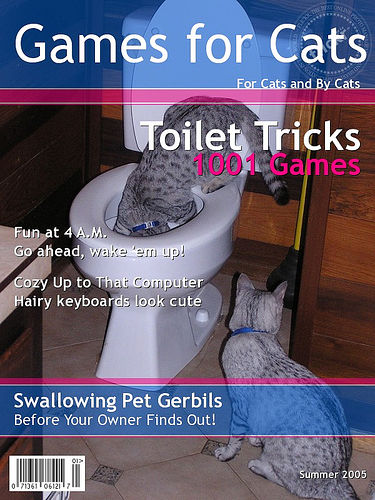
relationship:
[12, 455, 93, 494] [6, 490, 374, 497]
upc symbol on bottom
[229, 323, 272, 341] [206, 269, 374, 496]
collar on cat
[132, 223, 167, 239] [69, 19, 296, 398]
head in toilet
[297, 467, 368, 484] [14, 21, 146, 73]
date for game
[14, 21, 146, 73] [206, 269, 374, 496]
game for cat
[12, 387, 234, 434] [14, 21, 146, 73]
tagline for game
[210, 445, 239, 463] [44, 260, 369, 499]
left paw on floor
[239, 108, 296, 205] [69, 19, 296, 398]
tail hanging off toilet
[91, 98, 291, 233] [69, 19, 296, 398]
cat in toilet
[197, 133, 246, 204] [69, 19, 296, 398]
back legs on toilet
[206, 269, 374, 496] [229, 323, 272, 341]
cat has collar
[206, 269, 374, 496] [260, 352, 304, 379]
cat has spots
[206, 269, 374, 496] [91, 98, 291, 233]
cat by cat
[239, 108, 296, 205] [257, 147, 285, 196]
tail has stripes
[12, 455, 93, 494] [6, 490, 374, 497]
upc symbol at bottom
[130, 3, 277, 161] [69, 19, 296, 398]
lid to toilet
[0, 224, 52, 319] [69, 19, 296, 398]
countertop next to toilet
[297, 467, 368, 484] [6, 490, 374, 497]
date on bottom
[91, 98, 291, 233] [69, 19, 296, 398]
cat looking in toilet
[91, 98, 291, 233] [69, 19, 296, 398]
cat in a toilet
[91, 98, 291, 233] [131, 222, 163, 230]
cat has collar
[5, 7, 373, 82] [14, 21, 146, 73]
title for game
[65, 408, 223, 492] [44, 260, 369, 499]
tile on floor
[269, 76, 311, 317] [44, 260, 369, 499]
plunger on floor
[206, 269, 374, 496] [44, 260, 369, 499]
cat sitting on floor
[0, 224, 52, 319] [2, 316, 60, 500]
countertop on vanity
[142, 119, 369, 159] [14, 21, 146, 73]
toilet tricks for game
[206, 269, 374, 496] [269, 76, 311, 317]
cat looking at plunger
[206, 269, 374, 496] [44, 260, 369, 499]
cat on floor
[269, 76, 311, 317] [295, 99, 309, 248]
plunger has handle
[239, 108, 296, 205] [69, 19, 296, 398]
tail outside toilet